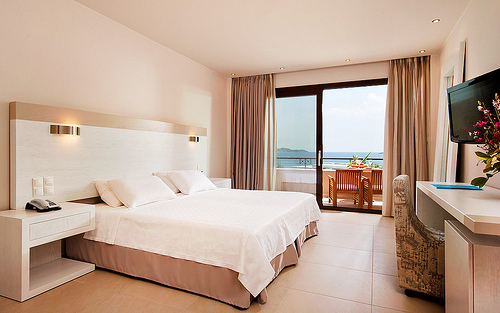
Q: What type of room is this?
A: Hotel room.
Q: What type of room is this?
A: Hotel room.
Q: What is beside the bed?
A: A bedside table.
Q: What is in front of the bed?
A: The television.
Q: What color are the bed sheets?
A: White.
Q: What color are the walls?
A: Beige.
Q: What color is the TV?
A: Black.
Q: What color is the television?
A: Black.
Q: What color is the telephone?
A: Black and white.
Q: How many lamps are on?
A: Two.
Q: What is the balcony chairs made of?
A: Wood.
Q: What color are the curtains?
A: Beige.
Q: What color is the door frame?
A: Black.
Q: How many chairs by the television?
A: 1.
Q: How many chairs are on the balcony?
A: 2.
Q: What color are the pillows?
A: White.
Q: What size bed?
A: King.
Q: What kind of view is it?
A: Ocean.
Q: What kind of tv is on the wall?
A: Flat screen.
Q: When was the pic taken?
A: During the day.